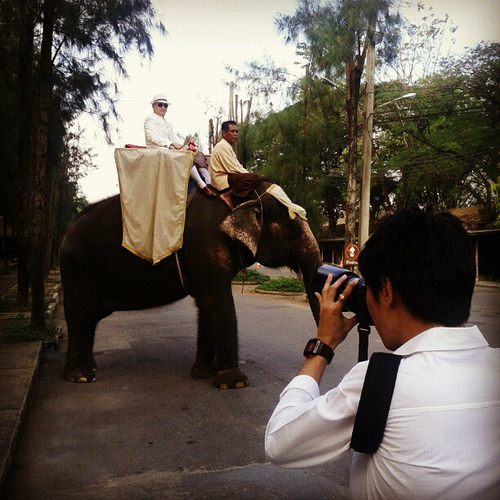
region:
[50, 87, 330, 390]
two guys on elephant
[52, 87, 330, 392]
two people riding an elephant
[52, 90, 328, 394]
two guys riding an elephant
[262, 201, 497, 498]
a person taking picture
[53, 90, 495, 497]
a guy taking picture of the elephant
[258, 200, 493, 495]
a person holding a camera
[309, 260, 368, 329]
a camera the guy is using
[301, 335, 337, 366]
watch on wrist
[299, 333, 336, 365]
a black watch the person is using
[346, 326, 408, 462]
a strap of the camera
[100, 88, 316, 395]
two men on elephant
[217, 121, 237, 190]
man has dark hair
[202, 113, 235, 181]
man has tan shirt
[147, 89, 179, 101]
man has white hat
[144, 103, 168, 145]
man has white shirt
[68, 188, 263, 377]
elephant is dark brown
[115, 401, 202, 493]
road is dark grey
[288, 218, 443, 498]
man is holding camera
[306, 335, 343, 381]
man has black watch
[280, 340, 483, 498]
man has white shirt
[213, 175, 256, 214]
he's sitting on the elephant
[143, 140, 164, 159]
he's sitting on the bench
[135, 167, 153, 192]
the cloth is light yellow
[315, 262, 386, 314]
he's taking a picture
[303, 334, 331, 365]
he's wearing a watch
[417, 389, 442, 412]
the shirt is white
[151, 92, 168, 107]
he's wearing a hat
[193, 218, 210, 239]
the elephant is brown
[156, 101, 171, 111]
he's wearing sunglasses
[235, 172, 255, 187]
the pants are brown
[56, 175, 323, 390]
Elephant on the road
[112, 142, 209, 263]
Seat on the elephant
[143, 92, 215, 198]
Man sitting on the seat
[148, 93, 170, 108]
Hat on the man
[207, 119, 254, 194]
Man sitting on the elephant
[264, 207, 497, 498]
Man taking picture of the elephant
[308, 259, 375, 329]
Camera in the man's hands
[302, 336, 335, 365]
Watch on the man's wrist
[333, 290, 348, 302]
Ring on the man's finger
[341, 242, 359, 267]
Road sign on a pole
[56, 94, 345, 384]
Two men ride an elephant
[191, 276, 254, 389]
Front legs of an elephant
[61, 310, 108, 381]
Back legs of an elephant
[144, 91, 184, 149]
A man in a white suit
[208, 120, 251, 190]
Man in yellow driving an elephant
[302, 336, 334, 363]
Black wristwatch on a man's arm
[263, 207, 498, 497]
A man in a white shirt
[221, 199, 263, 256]
Floppy ear on an elephant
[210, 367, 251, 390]
Foot of an elephant in the street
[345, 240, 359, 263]
A sign on the street